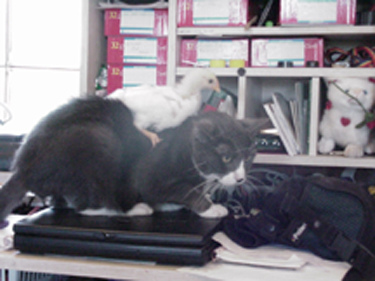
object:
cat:
[0, 94, 269, 229]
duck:
[102, 68, 221, 148]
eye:
[218, 150, 235, 166]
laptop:
[11, 203, 224, 267]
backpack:
[224, 172, 375, 279]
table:
[0, 206, 352, 281]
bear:
[317, 77, 375, 157]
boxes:
[103, 8, 169, 37]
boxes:
[107, 33, 170, 65]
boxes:
[180, 37, 249, 68]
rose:
[331, 80, 375, 128]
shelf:
[307, 67, 375, 169]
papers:
[260, 82, 308, 157]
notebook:
[211, 231, 333, 272]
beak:
[214, 85, 221, 93]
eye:
[207, 77, 213, 84]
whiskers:
[181, 168, 289, 215]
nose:
[234, 173, 244, 182]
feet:
[198, 200, 230, 220]